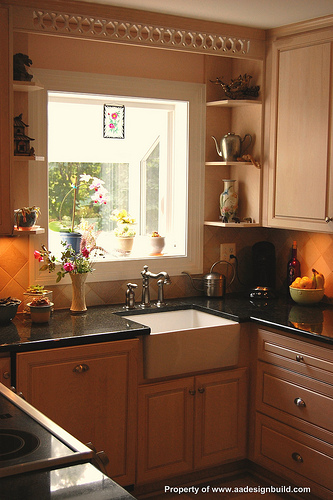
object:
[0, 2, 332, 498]
kitchen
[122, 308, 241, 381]
sink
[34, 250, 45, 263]
flowers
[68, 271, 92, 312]
vase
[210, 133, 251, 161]
teapot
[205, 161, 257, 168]
shelf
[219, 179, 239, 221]
vase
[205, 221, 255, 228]
shelf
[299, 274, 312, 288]
fruit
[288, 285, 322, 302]
bowl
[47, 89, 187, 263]
window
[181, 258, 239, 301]
watering can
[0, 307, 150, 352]
counter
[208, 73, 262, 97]
plant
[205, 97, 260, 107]
shelf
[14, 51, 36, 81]
sculpture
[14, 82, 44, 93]
shelf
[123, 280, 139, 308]
faucet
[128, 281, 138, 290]
handle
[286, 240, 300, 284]
bottle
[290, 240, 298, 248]
cork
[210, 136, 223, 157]
spout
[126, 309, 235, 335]
inside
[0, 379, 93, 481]
stove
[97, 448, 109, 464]
knob